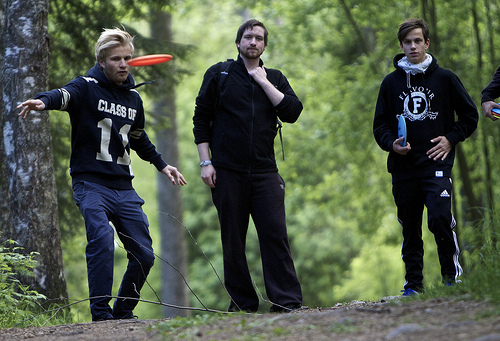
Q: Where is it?
A: This is at the forest.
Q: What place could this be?
A: It is a forest.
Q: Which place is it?
A: It is a forest.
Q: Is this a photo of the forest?
A: Yes, it is showing the forest.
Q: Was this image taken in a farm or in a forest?
A: It was taken at a forest.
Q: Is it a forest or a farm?
A: It is a forest.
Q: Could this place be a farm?
A: No, it is a forest.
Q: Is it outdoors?
A: Yes, it is outdoors.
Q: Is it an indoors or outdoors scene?
A: It is outdoors.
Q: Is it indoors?
A: No, it is outdoors.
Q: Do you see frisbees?
A: Yes, there is a frisbee.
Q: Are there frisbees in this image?
A: Yes, there is a frisbee.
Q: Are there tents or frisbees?
A: Yes, there is a frisbee.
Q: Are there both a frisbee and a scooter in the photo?
A: No, there is a frisbee but no scooters.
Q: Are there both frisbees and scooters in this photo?
A: No, there is a frisbee but no scooters.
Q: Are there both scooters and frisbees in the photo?
A: No, there is a frisbee but no scooters.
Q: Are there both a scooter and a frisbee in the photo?
A: No, there is a frisbee but no scooters.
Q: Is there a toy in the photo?
A: No, there are no toys.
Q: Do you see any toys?
A: No, there are no toys.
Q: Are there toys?
A: No, there are no toys.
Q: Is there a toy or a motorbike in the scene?
A: No, there are no toys or motorcycles.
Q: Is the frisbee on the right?
A: Yes, the frisbee is on the right of the image.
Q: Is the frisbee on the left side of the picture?
A: No, the frisbee is on the right of the image.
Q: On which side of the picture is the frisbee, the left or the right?
A: The frisbee is on the right of the image.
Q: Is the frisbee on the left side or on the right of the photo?
A: The frisbee is on the right of the image.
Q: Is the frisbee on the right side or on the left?
A: The frisbee is on the right of the image.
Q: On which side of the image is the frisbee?
A: The frisbee is on the right of the image.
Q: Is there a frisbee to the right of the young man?
A: Yes, there is a frisbee to the right of the man.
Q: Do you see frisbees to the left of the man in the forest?
A: No, the frisbee is to the right of the man.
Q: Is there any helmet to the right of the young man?
A: No, there is a frisbee to the right of the man.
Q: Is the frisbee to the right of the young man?
A: Yes, the frisbee is to the right of the man.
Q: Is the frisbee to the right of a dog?
A: No, the frisbee is to the right of the man.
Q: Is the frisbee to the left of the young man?
A: No, the frisbee is to the right of the man.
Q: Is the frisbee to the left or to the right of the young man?
A: The frisbee is to the right of the man.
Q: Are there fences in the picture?
A: No, there are no fences.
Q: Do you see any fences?
A: No, there are no fences.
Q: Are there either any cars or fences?
A: No, there are no fences or cars.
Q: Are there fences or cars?
A: No, there are no fences or cars.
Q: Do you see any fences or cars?
A: No, there are no fences or cars.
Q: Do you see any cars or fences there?
A: No, there are no fences or cars.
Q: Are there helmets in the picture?
A: No, there are no helmets.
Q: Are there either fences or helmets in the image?
A: No, there are no helmets or fences.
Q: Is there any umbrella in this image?
A: No, there are no umbrellas.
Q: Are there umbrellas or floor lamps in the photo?
A: No, there are no umbrellas or floor lamps.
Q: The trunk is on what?
A: The trunk is on the tree.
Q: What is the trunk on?
A: The trunk is on the tree.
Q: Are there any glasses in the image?
A: No, there are no glasses.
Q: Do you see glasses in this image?
A: No, there are no glasses.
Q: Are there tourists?
A: No, there are no tourists.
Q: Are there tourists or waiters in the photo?
A: No, there are no tourists or waiters.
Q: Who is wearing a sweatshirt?
A: The men are wearing a sweatshirt.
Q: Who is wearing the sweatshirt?
A: The men are wearing a sweatshirt.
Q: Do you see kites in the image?
A: No, there are no kites.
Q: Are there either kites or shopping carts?
A: No, there are no kites or shopping carts.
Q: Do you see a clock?
A: No, there are no clocks.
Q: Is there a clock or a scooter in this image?
A: No, there are no clocks or scooters.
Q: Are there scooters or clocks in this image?
A: No, there are no clocks or scooters.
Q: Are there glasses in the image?
A: No, there are no glasses.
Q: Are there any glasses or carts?
A: No, there are no glasses or carts.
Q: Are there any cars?
A: No, there are no cars.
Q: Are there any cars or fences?
A: No, there are no cars or fences.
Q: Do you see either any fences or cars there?
A: No, there are no cars or fences.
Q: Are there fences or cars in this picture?
A: No, there are no cars or fences.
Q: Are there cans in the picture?
A: No, there are no cans.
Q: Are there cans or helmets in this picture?
A: No, there are no cans or helmets.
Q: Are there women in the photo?
A: No, there are no women.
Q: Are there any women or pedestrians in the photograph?
A: No, there are no women or pedestrians.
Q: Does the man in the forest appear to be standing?
A: Yes, the man is standing.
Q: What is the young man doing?
A: The man is standing.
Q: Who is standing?
A: The man is standing.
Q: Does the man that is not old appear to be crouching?
A: No, the man is standing.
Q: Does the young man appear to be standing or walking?
A: The man is standing.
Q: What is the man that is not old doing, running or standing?
A: The man is standing.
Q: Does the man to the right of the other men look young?
A: Yes, the man is young.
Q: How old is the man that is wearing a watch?
A: The man is young.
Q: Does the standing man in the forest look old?
A: No, the man is young.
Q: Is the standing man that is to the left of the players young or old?
A: The man is young.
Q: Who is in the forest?
A: The man is in the forest.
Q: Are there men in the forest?
A: Yes, there is a man in the forest.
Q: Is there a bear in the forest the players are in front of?
A: No, there is a man in the forest.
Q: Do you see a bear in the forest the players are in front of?
A: No, there is a man in the forest.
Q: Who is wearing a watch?
A: The man is wearing a watch.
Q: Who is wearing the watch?
A: The man is wearing a watch.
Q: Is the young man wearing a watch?
A: Yes, the man is wearing a watch.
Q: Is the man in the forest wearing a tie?
A: No, the man is wearing a watch.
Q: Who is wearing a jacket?
A: The man is wearing a jacket.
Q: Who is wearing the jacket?
A: The man is wearing a jacket.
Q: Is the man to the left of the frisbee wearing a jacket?
A: Yes, the man is wearing a jacket.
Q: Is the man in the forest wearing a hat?
A: No, the man is wearing a jacket.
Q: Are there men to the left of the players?
A: Yes, there is a man to the left of the players.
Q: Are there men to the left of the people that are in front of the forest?
A: Yes, there is a man to the left of the players.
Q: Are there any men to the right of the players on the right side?
A: No, the man is to the left of the players.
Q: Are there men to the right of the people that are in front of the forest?
A: No, the man is to the left of the players.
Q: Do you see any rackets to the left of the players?
A: No, there is a man to the left of the players.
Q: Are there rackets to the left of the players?
A: No, there is a man to the left of the players.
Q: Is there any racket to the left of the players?
A: No, there is a man to the left of the players.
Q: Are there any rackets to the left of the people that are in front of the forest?
A: No, there is a man to the left of the players.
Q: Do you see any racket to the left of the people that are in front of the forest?
A: No, there is a man to the left of the players.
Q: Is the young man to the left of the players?
A: Yes, the man is to the left of the players.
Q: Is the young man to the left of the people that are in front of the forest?
A: Yes, the man is to the left of the players.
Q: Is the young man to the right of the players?
A: No, the man is to the left of the players.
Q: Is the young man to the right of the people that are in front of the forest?
A: No, the man is to the left of the players.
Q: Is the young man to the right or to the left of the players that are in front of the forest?
A: The man is to the left of the players.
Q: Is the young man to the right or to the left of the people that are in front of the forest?
A: The man is to the left of the players.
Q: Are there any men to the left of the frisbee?
A: Yes, there is a man to the left of the frisbee.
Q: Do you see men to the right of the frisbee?
A: No, the man is to the left of the frisbee.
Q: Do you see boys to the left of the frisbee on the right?
A: No, there is a man to the left of the frisbee.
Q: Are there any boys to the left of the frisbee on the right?
A: No, there is a man to the left of the frisbee.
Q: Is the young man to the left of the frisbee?
A: Yes, the man is to the left of the frisbee.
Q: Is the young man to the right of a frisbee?
A: No, the man is to the left of a frisbee.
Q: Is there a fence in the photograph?
A: No, there are no fences.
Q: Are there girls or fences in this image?
A: No, there are no fences or girls.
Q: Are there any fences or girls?
A: No, there are no fences or girls.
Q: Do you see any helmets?
A: No, there are no helmets.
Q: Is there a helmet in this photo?
A: No, there are no helmets.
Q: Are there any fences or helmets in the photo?
A: No, there are no helmets or fences.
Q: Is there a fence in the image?
A: No, there are no fences.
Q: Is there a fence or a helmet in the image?
A: No, there are no fences or helmets.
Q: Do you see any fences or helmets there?
A: No, there are no fences or helmets.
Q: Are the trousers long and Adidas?
A: Yes, the trousers are long and adidas.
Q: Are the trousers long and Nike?
A: No, the trousers are long but adidas.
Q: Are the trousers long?
A: Yes, the trousers are long.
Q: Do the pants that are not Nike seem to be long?
A: Yes, the pants are long.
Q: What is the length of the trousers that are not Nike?
A: The trousers are long.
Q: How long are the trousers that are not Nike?
A: The pants are long.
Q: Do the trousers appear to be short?
A: No, the trousers are long.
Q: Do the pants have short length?
A: No, the pants are long.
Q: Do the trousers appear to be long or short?
A: The trousers are long.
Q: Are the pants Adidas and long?
A: Yes, the pants are Adidas and long.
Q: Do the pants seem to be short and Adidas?
A: No, the pants are Adidas but long.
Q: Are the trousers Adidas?
A: Yes, the trousers are adidas.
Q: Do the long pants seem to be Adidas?
A: Yes, the trousers are adidas.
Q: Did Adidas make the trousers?
A: Yes, the trousers were made by adidas.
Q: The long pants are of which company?
A: The trousers are adidas.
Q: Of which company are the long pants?
A: The trousers are adidas.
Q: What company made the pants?
A: Adidas made adidas.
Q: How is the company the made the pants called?
A: The company is adidas.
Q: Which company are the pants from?
A: The pants are from adidas.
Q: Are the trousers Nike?
A: No, the trousers are adidas.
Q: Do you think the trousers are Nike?
A: No, the trousers are adidas.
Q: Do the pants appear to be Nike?
A: No, the pants are adidas.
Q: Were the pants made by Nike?
A: No, the pants were made by adidas.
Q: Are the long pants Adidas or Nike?
A: The trousers are adidas.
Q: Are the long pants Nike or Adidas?
A: The trousers are adidas.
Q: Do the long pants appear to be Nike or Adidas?
A: The trousers are adidas.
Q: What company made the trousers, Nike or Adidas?
A: The trousers were made adidas.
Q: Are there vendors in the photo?
A: No, there are no vendors.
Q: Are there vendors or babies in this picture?
A: No, there are no vendors or babies.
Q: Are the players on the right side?
A: Yes, the players are on the right of the image.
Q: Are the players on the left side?
A: No, the players are on the right of the image.